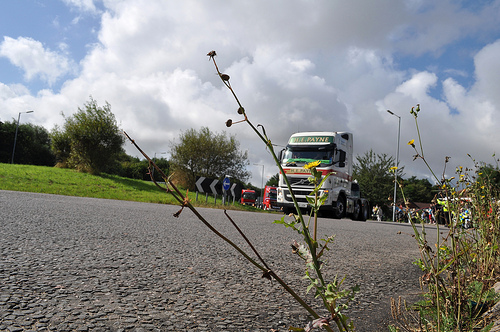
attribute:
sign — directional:
[181, 162, 241, 192]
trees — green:
[65, 102, 144, 177]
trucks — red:
[230, 184, 276, 214]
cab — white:
[267, 130, 355, 216]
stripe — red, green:
[277, 155, 333, 172]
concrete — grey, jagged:
[67, 226, 154, 278]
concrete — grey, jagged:
[67, 226, 177, 289]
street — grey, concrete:
[47, 241, 119, 259]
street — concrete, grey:
[90, 215, 147, 268]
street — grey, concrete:
[50, 190, 152, 264]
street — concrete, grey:
[93, 239, 194, 295]